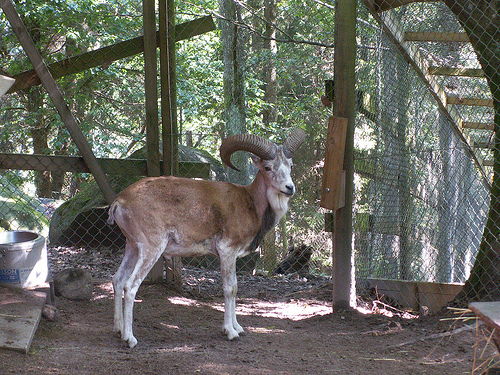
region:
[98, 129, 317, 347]
a goat standing next to a fence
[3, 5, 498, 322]
a tall fence next to the goat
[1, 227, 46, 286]
a bucket next to the fence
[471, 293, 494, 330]
part of a bench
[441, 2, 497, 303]
a tall tree on the other side of the fence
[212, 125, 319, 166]
the big horns of the goat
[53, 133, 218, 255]
a big rock with moss on it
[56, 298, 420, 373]
the dirt below the goat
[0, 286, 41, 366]
a piece of wood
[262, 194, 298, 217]
the chin hair on the goat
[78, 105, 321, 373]
the animal is brown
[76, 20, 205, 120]
the leaves are green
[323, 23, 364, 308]
the wood is brown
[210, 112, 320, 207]
the horns are curved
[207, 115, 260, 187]
the horn is sharp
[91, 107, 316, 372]
the animal is standing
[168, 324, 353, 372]
the dirt is brown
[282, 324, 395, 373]
the dirt is rough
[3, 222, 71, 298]
the bucket is white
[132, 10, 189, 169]
the boards are long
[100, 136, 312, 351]
the animal is brown in color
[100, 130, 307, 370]
the animal has curved horns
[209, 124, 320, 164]
the horns are grey in color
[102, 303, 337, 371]
the ground has dirt on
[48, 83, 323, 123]
there are trees in the background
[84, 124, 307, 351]
the animal is enclosed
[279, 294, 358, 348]
there is light reflection on the ground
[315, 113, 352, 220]
the wood is brown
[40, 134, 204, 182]
the rock is green in color moulds on it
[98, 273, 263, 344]
the feet are white in color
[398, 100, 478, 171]
part of a meshed fence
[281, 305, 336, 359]
part of a ground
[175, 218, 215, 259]
stomach of a ram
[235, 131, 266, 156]
right horn of a ram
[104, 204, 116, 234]
tail of the ram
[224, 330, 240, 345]
hoof of the ram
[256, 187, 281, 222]
neck of the ram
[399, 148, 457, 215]
part of a meshed fence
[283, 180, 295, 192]
nose of the ram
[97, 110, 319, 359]
the goat is standing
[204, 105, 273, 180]
the horn is bent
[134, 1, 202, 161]
the wood is brown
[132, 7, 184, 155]
the boards are wooden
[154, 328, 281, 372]
the ground is brown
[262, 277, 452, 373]
the ground is dirty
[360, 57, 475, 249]
the fence is gray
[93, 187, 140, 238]
the tail is short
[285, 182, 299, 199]
the nose is black